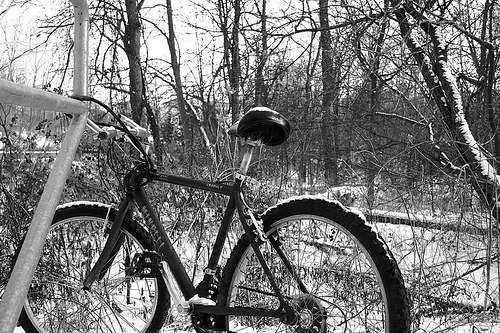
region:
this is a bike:
[0, 108, 417, 330]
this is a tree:
[399, 23, 499, 245]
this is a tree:
[344, 22, 404, 242]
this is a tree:
[298, 10, 365, 205]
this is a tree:
[218, 5, 261, 187]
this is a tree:
[115, 3, 155, 196]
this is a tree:
[154, 6, 215, 231]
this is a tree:
[248, 16, 324, 225]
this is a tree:
[365, 159, 475, 328]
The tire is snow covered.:
[260, 178, 407, 268]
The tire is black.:
[257, 188, 407, 331]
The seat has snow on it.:
[232, 96, 289, 137]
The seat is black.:
[219, 106, 295, 141]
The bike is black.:
[38, 98, 407, 328]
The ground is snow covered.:
[18, 173, 493, 330]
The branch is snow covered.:
[428, 53, 499, 200]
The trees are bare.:
[31, 19, 496, 184]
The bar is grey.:
[1, 5, 78, 331]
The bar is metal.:
[25, 1, 77, 320]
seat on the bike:
[209, 74, 308, 161]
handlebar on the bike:
[90, 119, 125, 154]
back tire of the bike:
[211, 175, 407, 312]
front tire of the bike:
[0, 200, 157, 327]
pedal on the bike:
[125, 238, 181, 289]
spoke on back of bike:
[309, 253, 369, 296]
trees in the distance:
[233, 38, 409, 103]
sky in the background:
[152, 28, 214, 78]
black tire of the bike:
[309, 190, 381, 247]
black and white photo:
[18, 70, 420, 299]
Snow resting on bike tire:
[282, 189, 350, 206]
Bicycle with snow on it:
[62, 93, 406, 330]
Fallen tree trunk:
[372, 199, 486, 230]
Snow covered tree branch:
[412, 49, 497, 196]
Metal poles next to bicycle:
[0, 33, 91, 331]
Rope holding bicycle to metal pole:
[77, 95, 119, 125]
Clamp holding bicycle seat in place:
[233, 169, 259, 187]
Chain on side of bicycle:
[239, 279, 276, 296]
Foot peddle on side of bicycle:
[129, 246, 159, 280]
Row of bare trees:
[100, 1, 496, 111]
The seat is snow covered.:
[218, 94, 292, 149]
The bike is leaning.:
[23, 88, 403, 331]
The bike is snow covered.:
[10, 74, 414, 329]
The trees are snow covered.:
[13, 6, 495, 201]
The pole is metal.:
[18, 15, 90, 327]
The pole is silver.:
[0, 2, 102, 330]